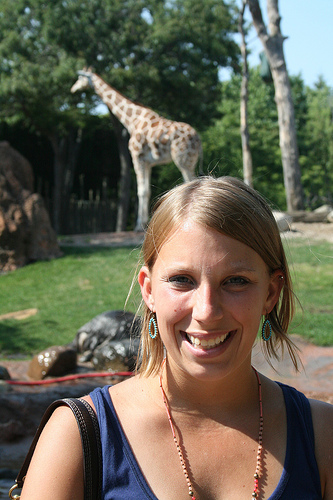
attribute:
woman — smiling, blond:
[13, 134, 321, 494]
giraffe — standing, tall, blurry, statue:
[67, 62, 208, 248]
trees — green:
[228, 9, 325, 234]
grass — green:
[7, 269, 113, 304]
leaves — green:
[5, 5, 223, 71]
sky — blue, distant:
[286, 6, 332, 74]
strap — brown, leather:
[20, 393, 104, 428]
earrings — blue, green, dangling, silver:
[145, 310, 161, 348]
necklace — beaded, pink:
[154, 355, 273, 500]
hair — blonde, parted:
[127, 166, 298, 265]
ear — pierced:
[128, 264, 161, 318]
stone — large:
[63, 299, 143, 369]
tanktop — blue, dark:
[78, 371, 327, 498]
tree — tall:
[234, 3, 259, 208]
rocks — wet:
[22, 299, 144, 383]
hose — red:
[6, 360, 128, 388]